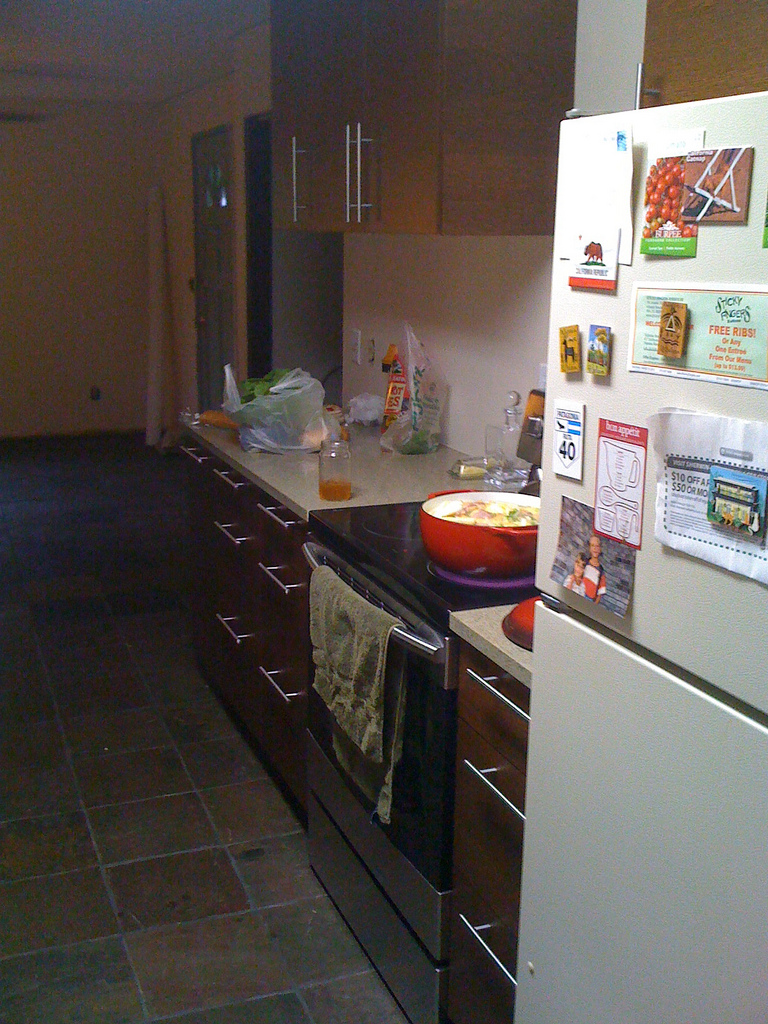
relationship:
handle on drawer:
[206, 508, 254, 553] [205, 510, 264, 627]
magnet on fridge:
[584, 412, 654, 551] [507, 85, 765, 1018]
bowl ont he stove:
[414, 465, 543, 586] [277, 490, 480, 970]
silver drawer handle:
[413, 631, 439, 651] [260, 663, 304, 706]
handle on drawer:
[456, 756, 523, 823] [443, 726, 526, 939]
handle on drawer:
[456, 911, 517, 985] [443, 878, 517, 1023]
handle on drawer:
[257, 555, 303, 595] [254, 551, 308, 638]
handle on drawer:
[213, 608, 249, 649] [211, 596, 261, 721]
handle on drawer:
[456, 911, 517, 985] [446, 864, 521, 1023]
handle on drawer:
[456, 756, 521, 826] [447, 710, 529, 923]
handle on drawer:
[460, 671, 529, 714] [450, 635, 537, 750]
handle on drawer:
[259, 663, 299, 706] [253, 642, 303, 792]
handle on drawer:
[215, 604, 252, 651] [211, 585, 252, 727]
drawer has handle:
[239, 526, 321, 660] [249, 553, 313, 614]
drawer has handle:
[243, 483, 318, 570] [247, 494, 302, 540]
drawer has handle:
[194, 494, 269, 579] [203, 498, 260, 567]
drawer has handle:
[197, 452, 259, 521] [198, 451, 253, 511]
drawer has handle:
[173, 424, 219, 489] [172, 438, 211, 475]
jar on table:
[311, 435, 357, 506] [170, 384, 526, 523]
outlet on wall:
[348, 321, 371, 376] [330, 5, 653, 492]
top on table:
[496, 590, 551, 650] [432, 594, 536, 688]